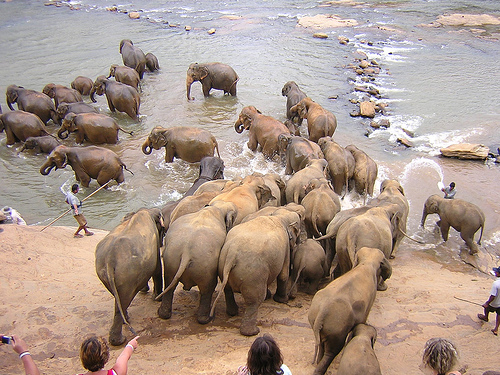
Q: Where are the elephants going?
A: To the water.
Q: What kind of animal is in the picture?
A: Elephants.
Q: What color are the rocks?
A: Brown.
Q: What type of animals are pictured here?
A: Elephants.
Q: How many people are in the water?
A: One.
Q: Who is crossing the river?
A: Elephants.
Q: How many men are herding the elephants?
A: 3.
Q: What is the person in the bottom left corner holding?
A: A camera.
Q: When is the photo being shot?
A: Daytime.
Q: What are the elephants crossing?
A: A river.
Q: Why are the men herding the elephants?
A: To cross the river.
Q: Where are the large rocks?
A: River.